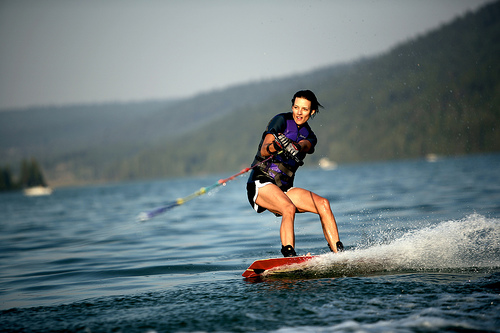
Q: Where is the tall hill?
A: Behind the woman.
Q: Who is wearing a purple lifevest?
A: A woman.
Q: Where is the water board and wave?
A: Under the woman.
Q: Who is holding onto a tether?
A: A woman.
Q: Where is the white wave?
A: In the water.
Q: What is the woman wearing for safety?
A: Life vest.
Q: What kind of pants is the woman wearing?
A: Shorts.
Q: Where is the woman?
A: River.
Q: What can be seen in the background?
A: Mountainside.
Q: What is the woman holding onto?
A: Rope.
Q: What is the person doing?
A: Water skiing.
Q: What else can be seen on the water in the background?
A: Boats.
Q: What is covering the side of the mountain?
A: Trees.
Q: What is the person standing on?
A: Water skis.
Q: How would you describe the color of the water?
A: Blue.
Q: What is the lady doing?
A: Playing.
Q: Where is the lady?
A: Water.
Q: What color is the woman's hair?
A: Black.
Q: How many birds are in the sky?
A: 0.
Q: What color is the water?
A: Blue.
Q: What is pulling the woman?
A: A boat.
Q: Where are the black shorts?
A: On the woman.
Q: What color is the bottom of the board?
A: Red.